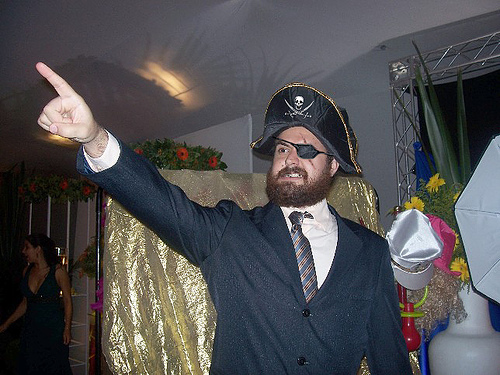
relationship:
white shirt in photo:
[295, 198, 337, 285] [13, 37, 496, 371]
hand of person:
[29, 49, 105, 148] [36, 56, 460, 374]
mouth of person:
[271, 162, 314, 181] [36, 56, 460, 374]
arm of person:
[372, 245, 416, 373] [36, 56, 460, 374]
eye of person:
[274, 143, 294, 156] [205, 69, 412, 344]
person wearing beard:
[36, 37, 459, 374] [230, 144, 357, 203]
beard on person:
[254, 162, 341, 207] [25, 26, 432, 341]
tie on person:
[282, 208, 322, 305] [36, 56, 460, 374]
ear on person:
[330, 155, 342, 176] [36, 56, 460, 374]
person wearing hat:
[36, 56, 460, 374] [262, 77, 400, 159]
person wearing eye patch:
[36, 56, 460, 374] [269, 130, 337, 168]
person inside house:
[36, 56, 460, 374] [1, 2, 497, 373]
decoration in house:
[125, 135, 230, 170] [0, 0, 500, 374]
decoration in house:
[0, 172, 97, 202] [0, 0, 500, 374]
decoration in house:
[66, 235, 98, 290] [0, 0, 500, 374]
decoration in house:
[402, 170, 469, 282] [0, 0, 500, 374]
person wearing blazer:
[36, 56, 460, 374] [79, 121, 422, 374]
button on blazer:
[298, 306, 311, 318] [68, 45, 433, 372]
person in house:
[36, 56, 460, 374] [0, 0, 500, 374]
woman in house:
[9, 229, 72, 374] [0, 0, 500, 374]